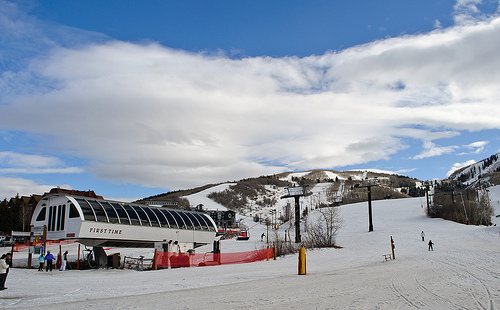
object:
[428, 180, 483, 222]
bush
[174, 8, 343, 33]
blue sky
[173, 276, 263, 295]
snow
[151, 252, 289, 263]
fence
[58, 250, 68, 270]
people standing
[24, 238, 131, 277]
front of building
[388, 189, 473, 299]
snow slope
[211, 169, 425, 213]
mountain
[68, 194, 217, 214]
roof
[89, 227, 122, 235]
words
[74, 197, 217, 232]
row of windows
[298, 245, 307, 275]
yellow pole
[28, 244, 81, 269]
line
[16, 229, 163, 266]
sky lift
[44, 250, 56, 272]
line of people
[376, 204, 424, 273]
snowy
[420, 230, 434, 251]
group of people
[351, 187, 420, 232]
slopes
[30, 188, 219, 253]
building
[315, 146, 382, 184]
this is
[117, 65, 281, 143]
cloud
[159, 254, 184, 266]
red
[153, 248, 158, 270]
pole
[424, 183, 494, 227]
this is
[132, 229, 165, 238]
white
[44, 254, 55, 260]
jacket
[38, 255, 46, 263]
jacket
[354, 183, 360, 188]
light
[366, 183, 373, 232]
pole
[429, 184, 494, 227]
tree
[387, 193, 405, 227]
hill top